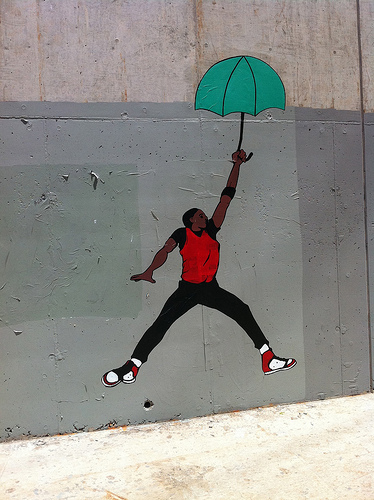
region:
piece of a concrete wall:
[20, 18, 169, 85]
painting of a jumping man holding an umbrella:
[98, 21, 351, 400]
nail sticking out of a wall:
[76, 159, 110, 185]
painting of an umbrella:
[185, 46, 310, 176]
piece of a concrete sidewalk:
[180, 434, 325, 490]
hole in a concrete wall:
[137, 390, 163, 416]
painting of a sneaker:
[251, 343, 309, 381]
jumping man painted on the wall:
[75, 137, 323, 394]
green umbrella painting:
[184, 28, 295, 172]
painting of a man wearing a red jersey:
[81, 134, 326, 404]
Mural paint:
[0, 47, 373, 406]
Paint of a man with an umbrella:
[79, 42, 311, 416]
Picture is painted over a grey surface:
[90, 41, 316, 427]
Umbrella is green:
[179, 45, 307, 165]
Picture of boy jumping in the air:
[98, 144, 305, 407]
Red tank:
[166, 224, 231, 289]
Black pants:
[119, 274, 278, 358]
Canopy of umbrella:
[180, 50, 294, 120]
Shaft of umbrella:
[232, 115, 250, 148]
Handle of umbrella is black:
[239, 148, 257, 166]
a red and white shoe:
[259, 346, 298, 377]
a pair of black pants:
[129, 278, 270, 362]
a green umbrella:
[191, 53, 288, 117]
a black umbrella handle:
[233, 110, 255, 163]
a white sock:
[257, 340, 269, 354]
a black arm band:
[221, 184, 236, 200]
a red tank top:
[178, 224, 221, 284]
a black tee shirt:
[168, 215, 227, 250]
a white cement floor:
[0, 390, 372, 498]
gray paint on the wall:
[0, 100, 373, 441]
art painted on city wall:
[89, 57, 292, 403]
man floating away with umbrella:
[84, 0, 310, 394]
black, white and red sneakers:
[98, 355, 152, 400]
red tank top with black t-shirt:
[147, 201, 228, 288]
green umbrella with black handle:
[175, 57, 294, 171]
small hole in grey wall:
[130, 388, 171, 423]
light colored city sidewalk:
[142, 420, 341, 496]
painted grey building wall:
[258, 172, 354, 301]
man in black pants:
[124, 264, 277, 371]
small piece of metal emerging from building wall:
[78, 161, 111, 193]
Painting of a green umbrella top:
[192, 55, 288, 116]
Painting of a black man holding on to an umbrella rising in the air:
[101, 53, 296, 399]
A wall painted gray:
[0, 101, 105, 442]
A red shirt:
[182, 235, 222, 285]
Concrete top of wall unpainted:
[1, 0, 373, 108]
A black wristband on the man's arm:
[221, 185, 239, 202]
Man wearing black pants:
[132, 280, 271, 356]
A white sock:
[129, 353, 145, 367]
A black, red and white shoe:
[101, 359, 142, 387]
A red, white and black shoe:
[261, 349, 300, 376]